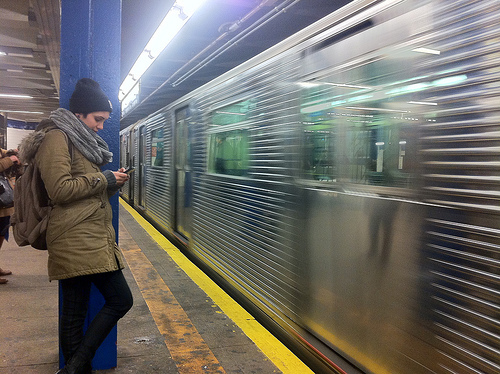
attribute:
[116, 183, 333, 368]
curb — yellow 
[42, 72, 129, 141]
hat — black 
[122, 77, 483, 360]
train — silver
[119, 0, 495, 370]
train — silver, fast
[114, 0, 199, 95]
flourescent lighting — fluorescent , overhead 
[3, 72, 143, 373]
girl — young 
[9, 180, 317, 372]
platform — yellow 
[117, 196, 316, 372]
caution line — yellow 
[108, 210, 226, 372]
caution line — yellow 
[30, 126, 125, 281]
coat — winter , brown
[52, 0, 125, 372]
beam — blue 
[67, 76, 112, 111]
hat — Black 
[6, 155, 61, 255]
backpack — full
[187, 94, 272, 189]
window — blurred 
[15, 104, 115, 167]
scarf — grey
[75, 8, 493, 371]
train — blurred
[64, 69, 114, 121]
hat — knit , black 